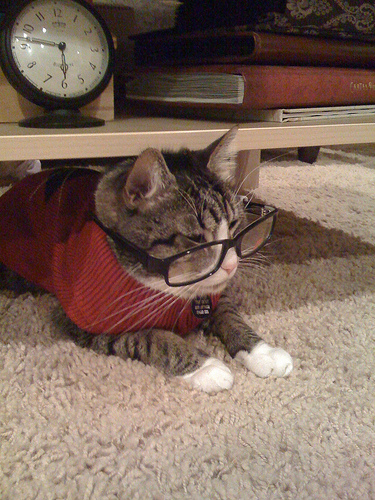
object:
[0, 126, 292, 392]
cat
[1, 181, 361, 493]
carpet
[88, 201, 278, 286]
eye glass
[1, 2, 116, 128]
clock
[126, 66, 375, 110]
books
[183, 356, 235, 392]
claws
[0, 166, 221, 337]
dress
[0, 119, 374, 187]
table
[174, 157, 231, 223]
stripes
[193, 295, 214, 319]
tag